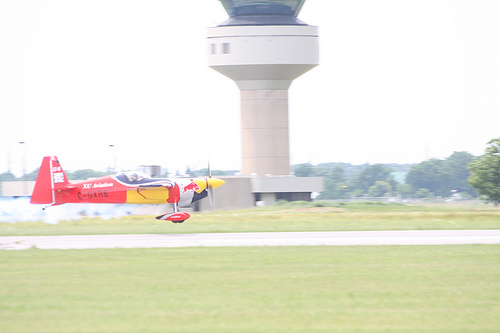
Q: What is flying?
A: A plane.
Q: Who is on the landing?
A: No one.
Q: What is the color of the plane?
A: Red and yellow.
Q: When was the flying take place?
A: Daytime.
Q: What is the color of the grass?
A: Green.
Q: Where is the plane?
A: At the airport.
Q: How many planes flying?
A: One.